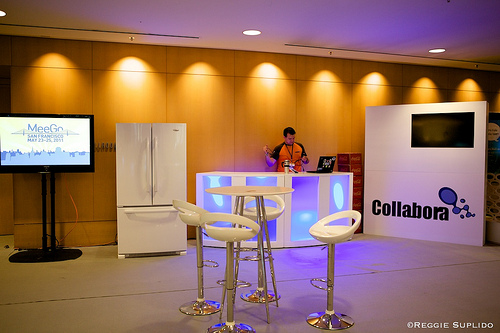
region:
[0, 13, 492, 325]
this appears to be some sort of exhibition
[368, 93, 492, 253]
this board says Collabora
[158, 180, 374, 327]
a high table & 4 ultra modern type chairs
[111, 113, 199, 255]
a double door refrigerator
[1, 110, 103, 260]
a flat screen tv on a pedestal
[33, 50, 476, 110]
the lights are coming from under the arches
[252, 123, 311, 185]
a man is behind the counter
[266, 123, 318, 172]
he wears an orange & black shirt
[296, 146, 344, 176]
a laptop is on the counter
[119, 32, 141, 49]
a fire sprinkler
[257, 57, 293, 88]
light on the wall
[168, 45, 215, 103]
light on the wall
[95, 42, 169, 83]
light on the wall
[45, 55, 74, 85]
light on the wall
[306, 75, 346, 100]
light on the wall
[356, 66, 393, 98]
light on the wall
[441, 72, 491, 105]
light on the wall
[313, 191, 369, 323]
stool on the floor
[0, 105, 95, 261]
Black television on a stand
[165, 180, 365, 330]
Four chairs and table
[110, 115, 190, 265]
White two door refrigerator with freezer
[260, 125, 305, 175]
Man wearing orange shirt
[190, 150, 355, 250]
Black laptop on counter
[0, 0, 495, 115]
Lights shining down from ceiling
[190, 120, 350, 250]
Man standing behind counter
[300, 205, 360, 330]
White and silver chair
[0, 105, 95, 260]
Flat screen television on a stand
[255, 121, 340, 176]
Man in orange shirt with laptop